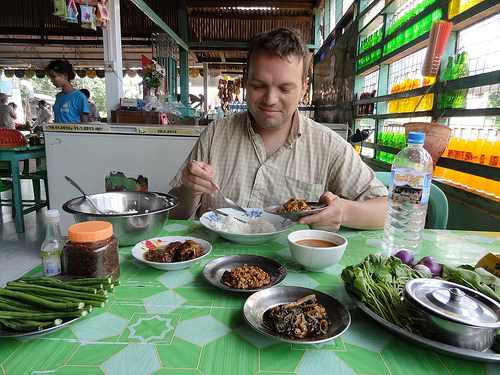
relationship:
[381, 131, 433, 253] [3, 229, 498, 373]
bottle placed table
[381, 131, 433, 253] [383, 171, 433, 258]
bottle of water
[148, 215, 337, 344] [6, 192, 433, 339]
food sitting on table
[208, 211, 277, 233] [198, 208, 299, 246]
white rice in bowl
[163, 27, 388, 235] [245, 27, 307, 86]
man with hair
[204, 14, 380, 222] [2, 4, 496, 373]
man dining in restaurant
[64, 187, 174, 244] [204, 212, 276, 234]
bowl of rice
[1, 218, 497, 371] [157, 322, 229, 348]
dining table covered with tablecloth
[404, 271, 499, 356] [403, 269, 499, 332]
dish with lid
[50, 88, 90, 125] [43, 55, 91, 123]
shirt on woman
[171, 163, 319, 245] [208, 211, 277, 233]
bowl of white rice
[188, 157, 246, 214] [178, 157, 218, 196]
spoon on hand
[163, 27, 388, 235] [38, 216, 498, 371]
man in front of table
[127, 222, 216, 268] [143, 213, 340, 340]
dish has food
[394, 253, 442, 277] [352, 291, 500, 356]
onions are in plate